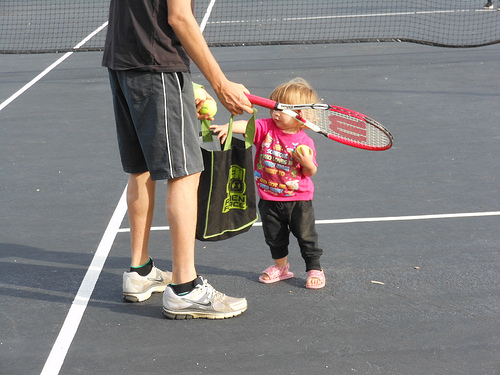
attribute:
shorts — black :
[106, 69, 203, 181]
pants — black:
[259, 201, 321, 271]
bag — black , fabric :
[179, 101, 270, 255]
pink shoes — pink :
[248, 250, 335, 299]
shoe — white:
[160, 275, 247, 323]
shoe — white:
[120, 267, 175, 302]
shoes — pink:
[306, 267, 323, 287]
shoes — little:
[258, 263, 293, 283]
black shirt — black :
[100, 3, 177, 71]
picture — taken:
[3, 4, 496, 366]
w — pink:
[319, 107, 371, 144]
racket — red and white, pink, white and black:
[245, 92, 392, 150]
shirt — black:
[98, 0, 198, 79]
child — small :
[210, 74, 327, 291]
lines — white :
[88, 210, 190, 278]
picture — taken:
[48, 0, 407, 346]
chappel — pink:
[247, 257, 332, 297]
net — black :
[18, 0, 469, 57]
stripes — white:
[158, 67, 189, 179]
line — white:
[319, 205, 490, 230]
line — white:
[32, 225, 138, 355]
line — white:
[7, 53, 84, 111]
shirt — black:
[99, 1, 190, 80]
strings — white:
[304, 106, 327, 129]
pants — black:
[256, 189, 335, 279]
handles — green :
[196, 101, 257, 148]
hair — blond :
[278, 79, 316, 128]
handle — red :
[250, 88, 271, 111]